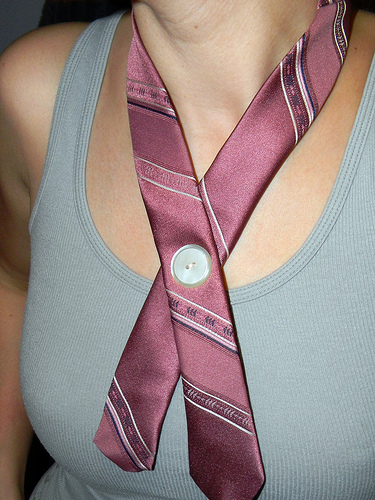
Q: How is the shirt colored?
A: Green.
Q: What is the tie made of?
A: Satin.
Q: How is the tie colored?
A: In pink.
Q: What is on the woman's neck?
A: Tie.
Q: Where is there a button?
A: On tie.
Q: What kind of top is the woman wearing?
A: Tank top.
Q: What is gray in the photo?
A: Tank top.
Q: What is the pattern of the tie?
A: Striped.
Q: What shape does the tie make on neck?
A: X shape.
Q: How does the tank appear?
A: Ribbed.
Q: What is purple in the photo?
A: TIe.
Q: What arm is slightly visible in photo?
A: Right arm.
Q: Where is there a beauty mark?
A: On neck.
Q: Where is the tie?
A: Around the woman's neck.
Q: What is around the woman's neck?
A: A tie.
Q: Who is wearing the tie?
A: The woman.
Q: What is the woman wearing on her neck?
A: A tie.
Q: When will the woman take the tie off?
A: When she is ready to take a shower.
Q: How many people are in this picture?
A: One.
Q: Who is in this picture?
A: A woman.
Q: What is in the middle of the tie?
A: A button.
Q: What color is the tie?
A: Maroon and white.